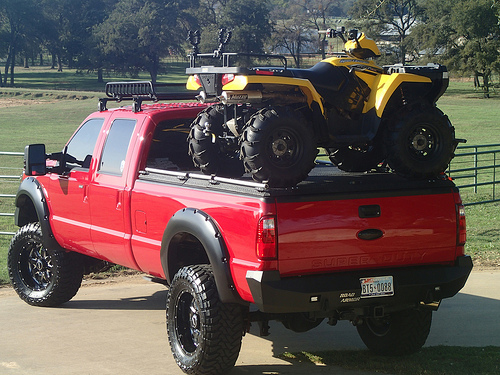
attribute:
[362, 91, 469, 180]
tire — black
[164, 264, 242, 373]
wheel — large, black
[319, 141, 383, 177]
tire — black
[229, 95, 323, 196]
tire — black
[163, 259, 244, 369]
tire — black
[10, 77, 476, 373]
truck — red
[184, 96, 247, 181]
tire — black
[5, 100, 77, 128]
grass — green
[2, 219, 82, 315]
tire — black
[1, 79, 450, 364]
truck — red